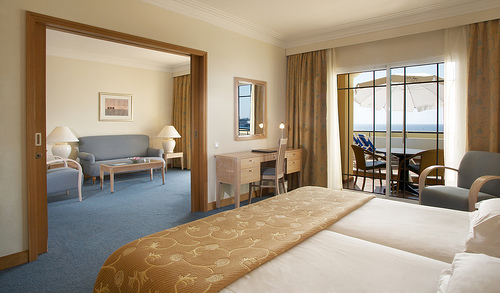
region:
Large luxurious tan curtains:
[285, 8, 498, 191]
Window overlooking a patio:
[332, 54, 446, 203]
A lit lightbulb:
[278, 121, 285, 131]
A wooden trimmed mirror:
[231, 75, 268, 141]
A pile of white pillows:
[439, 195, 496, 290]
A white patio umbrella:
[352, 73, 452, 146]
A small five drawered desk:
[214, 145, 304, 212]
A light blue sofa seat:
[75, 134, 165, 183]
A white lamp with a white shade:
[157, 124, 179, 154]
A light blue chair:
[418, 150, 498, 211]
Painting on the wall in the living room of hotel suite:
[95, 91, 135, 123]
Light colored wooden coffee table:
[96, 156, 167, 193]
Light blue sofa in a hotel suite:
[79, 129, 164, 179]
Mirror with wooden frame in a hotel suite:
[232, 76, 267, 140]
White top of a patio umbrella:
[355, 72, 444, 112]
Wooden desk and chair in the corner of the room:
[215, 138, 306, 206]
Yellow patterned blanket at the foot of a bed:
[91, 183, 376, 288]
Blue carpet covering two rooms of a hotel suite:
[1, 165, 183, 288]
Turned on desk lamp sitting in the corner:
[276, 119, 288, 145]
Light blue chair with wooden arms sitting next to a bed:
[416, 148, 498, 208]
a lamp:
[155, 123, 190, 160]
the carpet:
[75, 205, 143, 240]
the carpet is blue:
[65, 200, 124, 240]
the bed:
[229, 199, 421, 285]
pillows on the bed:
[442, 249, 492, 287]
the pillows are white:
[438, 258, 490, 290]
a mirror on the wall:
[239, 81, 261, 136]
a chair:
[349, 138, 371, 168]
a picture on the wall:
[97, 91, 139, 123]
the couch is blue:
[80, 134, 150, 151]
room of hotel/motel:
[0, 3, 499, 292]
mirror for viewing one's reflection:
[233, 78, 269, 138]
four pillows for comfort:
[434, 193, 498, 291]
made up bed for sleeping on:
[96, 182, 499, 291]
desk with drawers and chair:
[215, 141, 305, 181]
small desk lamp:
[279, 122, 287, 149]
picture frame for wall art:
[98, 89, 135, 123]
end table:
[163, 152, 184, 168]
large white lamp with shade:
[156, 123, 181, 152]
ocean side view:
[336, 66, 447, 186]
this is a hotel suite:
[153, 89, 436, 279]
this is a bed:
[234, 147, 310, 268]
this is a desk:
[226, 151, 286, 208]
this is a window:
[314, 82, 396, 162]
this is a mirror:
[158, 72, 319, 152]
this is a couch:
[60, 62, 184, 285]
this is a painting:
[83, 79, 165, 132]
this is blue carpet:
[113, 203, 167, 250]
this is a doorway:
[7, 137, 265, 213]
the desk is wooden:
[223, 151, 270, 199]